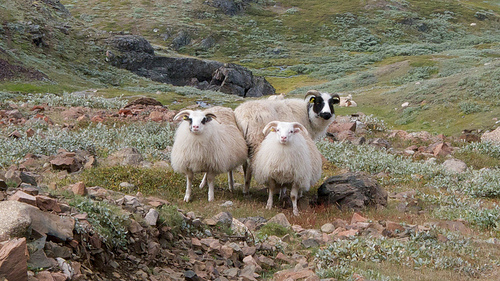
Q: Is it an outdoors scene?
A: Yes, it is outdoors.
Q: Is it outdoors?
A: Yes, it is outdoors.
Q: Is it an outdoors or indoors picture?
A: It is outdoors.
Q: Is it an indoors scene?
A: No, it is outdoors.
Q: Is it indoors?
A: No, it is outdoors.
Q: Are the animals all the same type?
A: Yes, all the animals are goats.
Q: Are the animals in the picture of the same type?
A: Yes, all the animals are goats.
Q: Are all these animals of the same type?
A: Yes, all the animals are goats.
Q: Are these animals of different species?
A: No, all the animals are goats.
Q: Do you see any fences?
A: No, there are no fences.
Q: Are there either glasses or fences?
A: No, there are no fences or glasses.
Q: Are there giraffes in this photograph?
A: No, there are no giraffes.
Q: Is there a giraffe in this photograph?
A: No, there are no giraffes.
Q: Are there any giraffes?
A: No, there are no giraffes.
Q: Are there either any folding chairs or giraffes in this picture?
A: No, there are no giraffes or folding chairs.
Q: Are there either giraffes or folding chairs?
A: No, there are no giraffes or folding chairs.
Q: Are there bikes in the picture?
A: No, there are no bikes.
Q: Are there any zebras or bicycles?
A: No, there are no bicycles or zebras.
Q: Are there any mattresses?
A: No, there are no mattresses.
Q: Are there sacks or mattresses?
A: No, there are no mattresses or sacks.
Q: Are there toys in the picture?
A: No, there are no toys.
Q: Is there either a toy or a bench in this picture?
A: No, there are no toys or benches.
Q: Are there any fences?
A: No, there are no fences.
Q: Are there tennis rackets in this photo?
A: No, there are no tennis rackets.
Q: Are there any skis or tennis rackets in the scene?
A: No, there are no tennis rackets or skis.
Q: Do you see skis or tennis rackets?
A: No, there are no tennis rackets or skis.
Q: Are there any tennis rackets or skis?
A: No, there are no tennis rackets or skis.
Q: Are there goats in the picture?
A: Yes, there is a goat.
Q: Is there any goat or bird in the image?
A: Yes, there is a goat.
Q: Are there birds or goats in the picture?
A: Yes, there is a goat.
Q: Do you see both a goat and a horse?
A: No, there is a goat but no horses.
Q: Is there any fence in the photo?
A: No, there are no fences.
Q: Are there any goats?
A: Yes, there is a goat.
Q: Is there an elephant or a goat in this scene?
A: Yes, there is a goat.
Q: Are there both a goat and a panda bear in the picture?
A: No, there is a goat but no pandas.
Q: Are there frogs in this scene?
A: No, there are no frogs.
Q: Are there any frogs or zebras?
A: No, there are no frogs or zebras.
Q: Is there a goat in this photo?
A: Yes, there is a goat.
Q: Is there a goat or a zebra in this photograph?
A: Yes, there is a goat.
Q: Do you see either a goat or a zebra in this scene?
A: Yes, there is a goat.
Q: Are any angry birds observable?
A: No, there are no angry birds.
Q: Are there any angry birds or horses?
A: No, there are no angry birds or horses.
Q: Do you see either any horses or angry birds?
A: No, there are no angry birds or horses.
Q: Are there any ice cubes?
A: No, there are no ice cubes.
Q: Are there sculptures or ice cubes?
A: No, there are no ice cubes or sculptures.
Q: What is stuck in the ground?
A: The rock is stuck in the ground.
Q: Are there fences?
A: No, there are no fences.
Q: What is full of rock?
A: The ground is full of rock.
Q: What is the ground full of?
A: The ground is full of rock.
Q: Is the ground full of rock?
A: Yes, the ground is full of rock.